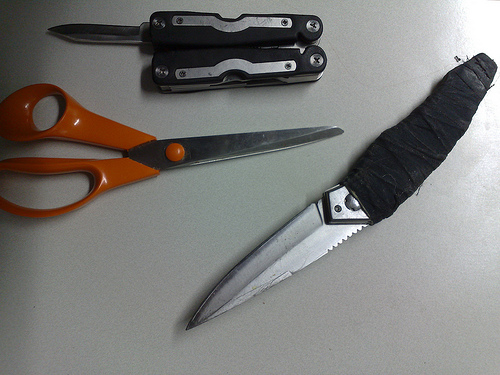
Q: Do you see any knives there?
A: Yes, there is a knife.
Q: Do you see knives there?
A: Yes, there is a knife.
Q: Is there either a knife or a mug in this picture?
A: Yes, there is a knife.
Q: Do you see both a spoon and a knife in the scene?
A: No, there is a knife but no spoons.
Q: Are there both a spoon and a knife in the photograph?
A: No, there is a knife but no spoons.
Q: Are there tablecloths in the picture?
A: No, there are no tablecloths.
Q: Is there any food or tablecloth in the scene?
A: No, there are no tablecloths or food.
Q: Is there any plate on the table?
A: No, there is a knife on the table.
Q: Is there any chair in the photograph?
A: No, there are no chairs.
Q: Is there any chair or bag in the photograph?
A: No, there are no chairs or bags.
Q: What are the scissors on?
A: The scissors are on the table.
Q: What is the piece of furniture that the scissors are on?
A: The piece of furniture is a table.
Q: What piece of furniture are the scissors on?
A: The scissors are on the table.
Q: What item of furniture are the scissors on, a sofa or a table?
A: The scissors are on a table.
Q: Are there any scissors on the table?
A: Yes, there are scissors on the table.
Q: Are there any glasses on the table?
A: No, there are scissors on the table.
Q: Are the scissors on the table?
A: Yes, the scissors are on the table.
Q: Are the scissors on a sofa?
A: No, the scissors are on the table.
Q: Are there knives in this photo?
A: Yes, there is a knife.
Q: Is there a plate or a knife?
A: Yes, there is a knife.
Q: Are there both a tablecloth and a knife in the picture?
A: No, there is a knife but no tablecloths.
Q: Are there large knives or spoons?
A: Yes, there is a large knife.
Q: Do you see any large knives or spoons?
A: Yes, there is a large knife.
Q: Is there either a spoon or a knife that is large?
A: Yes, the knife is large.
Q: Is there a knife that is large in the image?
A: Yes, there is a large knife.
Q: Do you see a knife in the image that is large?
A: Yes, there is a knife that is large.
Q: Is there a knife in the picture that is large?
A: Yes, there is a knife that is large.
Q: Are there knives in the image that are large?
A: Yes, there is a knife that is large.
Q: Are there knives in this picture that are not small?
A: Yes, there is a large knife.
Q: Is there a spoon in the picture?
A: No, there are no spoons.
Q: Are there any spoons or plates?
A: No, there are no spoons or plates.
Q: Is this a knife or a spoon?
A: This is a knife.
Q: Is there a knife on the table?
A: Yes, there is a knife on the table.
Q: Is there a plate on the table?
A: No, there is a knife on the table.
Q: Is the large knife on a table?
A: Yes, the knife is on a table.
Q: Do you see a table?
A: Yes, there is a table.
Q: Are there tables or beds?
A: Yes, there is a table.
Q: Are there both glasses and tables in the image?
A: No, there is a table but no glasses.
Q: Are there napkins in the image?
A: No, there are no napkins.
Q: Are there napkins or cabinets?
A: No, there are no napkins or cabinets.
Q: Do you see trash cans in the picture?
A: No, there are no trash cans.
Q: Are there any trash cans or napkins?
A: No, there are no trash cans or napkins.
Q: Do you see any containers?
A: No, there are no containers.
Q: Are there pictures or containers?
A: No, there are no containers or pictures.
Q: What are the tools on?
A: The tools are on the table.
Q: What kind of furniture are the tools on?
A: The tools are on the table.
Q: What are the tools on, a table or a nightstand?
A: The tools are on a table.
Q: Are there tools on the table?
A: Yes, there are tools on the table.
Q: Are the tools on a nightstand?
A: No, the tools are on the table.